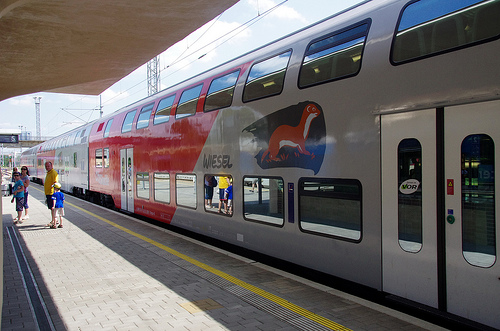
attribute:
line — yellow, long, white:
[28, 178, 350, 330]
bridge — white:
[2, 139, 41, 152]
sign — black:
[2, 133, 19, 144]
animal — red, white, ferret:
[260, 102, 323, 167]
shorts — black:
[44, 192, 55, 209]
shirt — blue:
[50, 192, 66, 209]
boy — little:
[50, 181, 66, 229]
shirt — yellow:
[44, 172, 60, 196]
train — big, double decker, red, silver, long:
[16, 0, 497, 330]